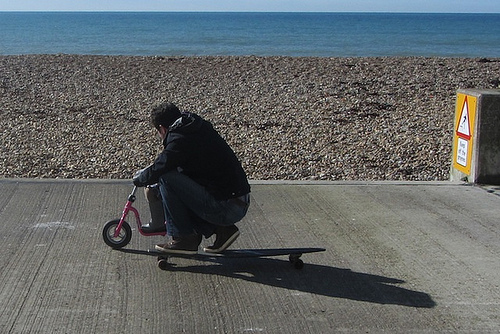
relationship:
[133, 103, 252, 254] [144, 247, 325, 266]
man on skateboard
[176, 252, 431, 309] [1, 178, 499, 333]
shadow on concrete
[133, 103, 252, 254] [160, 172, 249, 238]
man wearing jeans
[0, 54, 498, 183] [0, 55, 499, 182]
beach has pebbles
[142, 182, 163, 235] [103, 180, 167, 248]
child on scooter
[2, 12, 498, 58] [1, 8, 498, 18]
water goes to horizon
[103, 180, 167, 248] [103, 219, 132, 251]
scooter has tire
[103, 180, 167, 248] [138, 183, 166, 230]
scooter has a leg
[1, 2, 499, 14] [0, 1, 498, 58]
sky light blue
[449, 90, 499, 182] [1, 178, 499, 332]
post on concrete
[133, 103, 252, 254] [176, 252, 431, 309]
man has a shadow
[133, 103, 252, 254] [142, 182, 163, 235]
man helping child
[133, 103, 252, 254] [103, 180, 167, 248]
man holding scooter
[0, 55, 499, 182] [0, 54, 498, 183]
pebbles are on beach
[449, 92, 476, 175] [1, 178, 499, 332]
sign on concrete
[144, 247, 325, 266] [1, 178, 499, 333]
skateboard on concrete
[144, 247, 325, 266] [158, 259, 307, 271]
skateboard has wheels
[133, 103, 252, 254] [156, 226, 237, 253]
man wearing shoes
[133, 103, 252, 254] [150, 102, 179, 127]
man has hair